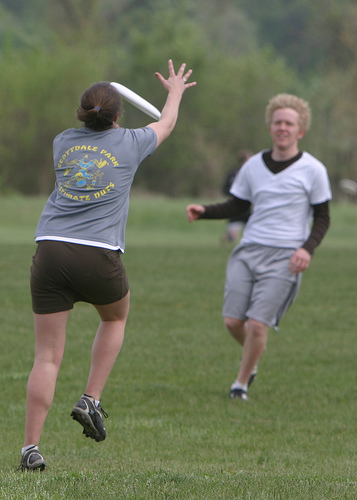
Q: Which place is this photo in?
A: It is at the field.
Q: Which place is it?
A: It is a field.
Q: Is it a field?
A: Yes, it is a field.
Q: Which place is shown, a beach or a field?
A: It is a field.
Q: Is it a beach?
A: No, it is a field.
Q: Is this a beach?
A: No, it is a field.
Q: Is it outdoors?
A: Yes, it is outdoors.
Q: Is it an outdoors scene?
A: Yes, it is outdoors.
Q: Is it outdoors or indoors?
A: It is outdoors.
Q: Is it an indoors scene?
A: No, it is outdoors.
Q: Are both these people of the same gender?
A: No, they are both male and female.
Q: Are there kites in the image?
A: No, there are no kites.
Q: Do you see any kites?
A: No, there are no kites.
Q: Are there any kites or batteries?
A: No, there are no kites or batteries.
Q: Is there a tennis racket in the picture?
A: No, there are no rackets.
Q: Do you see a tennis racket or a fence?
A: No, there are no rackets or fences.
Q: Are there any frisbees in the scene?
A: Yes, there is a frisbee.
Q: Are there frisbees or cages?
A: Yes, there is a frisbee.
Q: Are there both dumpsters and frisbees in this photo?
A: No, there is a frisbee but no dumpsters.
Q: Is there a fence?
A: No, there are no fences.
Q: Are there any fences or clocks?
A: No, there are no fences or clocks.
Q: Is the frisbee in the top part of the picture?
A: Yes, the frisbee is in the top of the image.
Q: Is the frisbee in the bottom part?
A: No, the frisbee is in the top of the image.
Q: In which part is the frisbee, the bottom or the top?
A: The frisbee is in the top of the image.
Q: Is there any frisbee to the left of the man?
A: Yes, there is a frisbee to the left of the man.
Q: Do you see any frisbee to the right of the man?
A: No, the frisbee is to the left of the man.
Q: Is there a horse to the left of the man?
A: No, there is a frisbee to the left of the man.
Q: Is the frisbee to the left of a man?
A: Yes, the frisbee is to the left of a man.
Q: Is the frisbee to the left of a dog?
A: No, the frisbee is to the left of a man.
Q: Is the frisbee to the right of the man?
A: No, the frisbee is to the left of the man.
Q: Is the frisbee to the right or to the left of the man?
A: The frisbee is to the left of the man.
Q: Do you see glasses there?
A: No, there are no glasses.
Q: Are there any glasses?
A: No, there are no glasses.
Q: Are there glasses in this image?
A: No, there are no glasses.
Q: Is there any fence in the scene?
A: No, there are no fences.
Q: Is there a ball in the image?
A: No, there are no balls.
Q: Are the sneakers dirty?
A: Yes, the sneakers are dirty.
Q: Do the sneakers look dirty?
A: Yes, the sneakers are dirty.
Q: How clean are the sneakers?
A: The sneakers are dirty.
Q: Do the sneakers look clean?
A: No, the sneakers are dirty.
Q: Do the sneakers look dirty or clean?
A: The sneakers are dirty.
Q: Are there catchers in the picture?
A: No, there are no catchers.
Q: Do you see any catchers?
A: No, there are no catchers.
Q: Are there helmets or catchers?
A: No, there are no catchers or helmets.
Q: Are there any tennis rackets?
A: No, there are no tennis rackets.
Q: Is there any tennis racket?
A: No, there are no rackets.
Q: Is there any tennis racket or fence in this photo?
A: No, there are no rackets or fences.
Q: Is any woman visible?
A: Yes, there is a woman.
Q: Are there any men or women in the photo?
A: Yes, there is a woman.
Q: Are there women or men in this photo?
A: Yes, there is a woman.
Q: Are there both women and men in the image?
A: Yes, there are both a woman and a man.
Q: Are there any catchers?
A: No, there are no catchers.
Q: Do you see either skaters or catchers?
A: No, there are no catchers or skaters.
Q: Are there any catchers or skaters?
A: No, there are no catchers or skaters.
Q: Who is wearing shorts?
A: The woman is wearing shorts.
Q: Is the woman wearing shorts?
A: Yes, the woman is wearing shorts.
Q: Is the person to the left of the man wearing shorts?
A: Yes, the woman is wearing shorts.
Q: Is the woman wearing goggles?
A: No, the woman is wearing shorts.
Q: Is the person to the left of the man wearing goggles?
A: No, the woman is wearing shorts.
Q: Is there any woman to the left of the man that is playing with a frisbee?
A: Yes, there is a woman to the left of the man.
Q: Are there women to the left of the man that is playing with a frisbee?
A: Yes, there is a woman to the left of the man.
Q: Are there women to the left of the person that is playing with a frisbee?
A: Yes, there is a woman to the left of the man.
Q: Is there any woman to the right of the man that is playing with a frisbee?
A: No, the woman is to the left of the man.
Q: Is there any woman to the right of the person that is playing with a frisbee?
A: No, the woman is to the left of the man.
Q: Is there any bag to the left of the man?
A: No, there is a woman to the left of the man.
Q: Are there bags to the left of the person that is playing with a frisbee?
A: No, there is a woman to the left of the man.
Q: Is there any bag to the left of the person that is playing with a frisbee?
A: No, there is a woman to the left of the man.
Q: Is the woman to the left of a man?
A: Yes, the woman is to the left of a man.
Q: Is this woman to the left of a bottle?
A: No, the woman is to the left of a man.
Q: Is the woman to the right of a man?
A: No, the woman is to the left of a man.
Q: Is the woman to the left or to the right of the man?
A: The woman is to the left of the man.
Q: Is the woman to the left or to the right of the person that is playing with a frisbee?
A: The woman is to the left of the man.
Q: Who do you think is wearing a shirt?
A: The woman is wearing a shirt.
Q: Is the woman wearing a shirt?
A: Yes, the woman is wearing a shirt.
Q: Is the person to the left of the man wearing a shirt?
A: Yes, the woman is wearing a shirt.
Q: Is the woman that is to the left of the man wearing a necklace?
A: No, the woman is wearing a shirt.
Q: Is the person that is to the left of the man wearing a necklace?
A: No, the woman is wearing a shirt.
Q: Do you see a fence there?
A: No, there are no fences.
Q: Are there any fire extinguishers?
A: No, there are no fire extinguishers.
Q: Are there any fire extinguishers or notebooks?
A: No, there are no fire extinguishers or notebooks.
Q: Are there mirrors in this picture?
A: No, there are no mirrors.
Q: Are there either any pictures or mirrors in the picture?
A: No, there are no mirrors or pictures.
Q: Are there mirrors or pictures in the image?
A: No, there are no mirrors or pictures.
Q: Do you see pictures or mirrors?
A: No, there are no mirrors or pictures.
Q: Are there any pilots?
A: No, there are no pilots.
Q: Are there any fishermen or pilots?
A: No, there are no pilots or fishermen.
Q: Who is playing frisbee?
A: The man is playing frisbee.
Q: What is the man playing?
A: The man is playing frisbee.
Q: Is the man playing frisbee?
A: Yes, the man is playing frisbee.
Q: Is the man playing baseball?
A: No, the man is playing frisbee.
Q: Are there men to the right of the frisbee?
A: Yes, there is a man to the right of the frisbee.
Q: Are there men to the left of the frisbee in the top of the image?
A: No, the man is to the right of the frisbee.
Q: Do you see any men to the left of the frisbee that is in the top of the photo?
A: No, the man is to the right of the frisbee.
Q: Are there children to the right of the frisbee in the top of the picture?
A: No, there is a man to the right of the frisbee.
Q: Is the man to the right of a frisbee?
A: Yes, the man is to the right of a frisbee.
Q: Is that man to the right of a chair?
A: No, the man is to the right of a frisbee.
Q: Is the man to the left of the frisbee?
A: No, the man is to the right of the frisbee.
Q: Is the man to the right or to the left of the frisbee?
A: The man is to the right of the frisbee.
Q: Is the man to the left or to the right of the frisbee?
A: The man is to the right of the frisbee.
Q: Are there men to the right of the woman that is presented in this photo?
A: Yes, there is a man to the right of the woman.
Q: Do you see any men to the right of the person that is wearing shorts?
A: Yes, there is a man to the right of the woman.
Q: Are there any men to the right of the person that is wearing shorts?
A: Yes, there is a man to the right of the woman.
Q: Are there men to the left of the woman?
A: No, the man is to the right of the woman.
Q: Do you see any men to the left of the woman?
A: No, the man is to the right of the woman.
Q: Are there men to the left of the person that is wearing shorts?
A: No, the man is to the right of the woman.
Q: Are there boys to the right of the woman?
A: No, there is a man to the right of the woman.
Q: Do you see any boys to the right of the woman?
A: No, there is a man to the right of the woman.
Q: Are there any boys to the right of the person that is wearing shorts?
A: No, there is a man to the right of the woman.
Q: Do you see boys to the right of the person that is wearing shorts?
A: No, there is a man to the right of the woman.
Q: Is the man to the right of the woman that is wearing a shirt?
A: Yes, the man is to the right of the woman.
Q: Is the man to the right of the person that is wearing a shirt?
A: Yes, the man is to the right of the woman.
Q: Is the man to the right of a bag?
A: No, the man is to the right of the woman.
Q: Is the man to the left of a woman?
A: No, the man is to the right of a woman.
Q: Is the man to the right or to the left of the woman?
A: The man is to the right of the woman.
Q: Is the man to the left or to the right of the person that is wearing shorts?
A: The man is to the right of the woman.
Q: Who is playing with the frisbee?
A: The man is playing with the frisbee.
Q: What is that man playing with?
A: The man is playing with a frisbee.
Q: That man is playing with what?
A: The man is playing with a frisbee.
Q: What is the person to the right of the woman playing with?
A: The man is playing with a frisbee.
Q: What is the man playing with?
A: The man is playing with a frisbee.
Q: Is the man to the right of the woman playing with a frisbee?
A: Yes, the man is playing with a frisbee.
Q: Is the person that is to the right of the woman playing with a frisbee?
A: Yes, the man is playing with a frisbee.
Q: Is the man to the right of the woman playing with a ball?
A: No, the man is playing with a frisbee.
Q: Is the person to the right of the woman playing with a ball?
A: No, the man is playing with a frisbee.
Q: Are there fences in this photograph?
A: No, there are no fences.